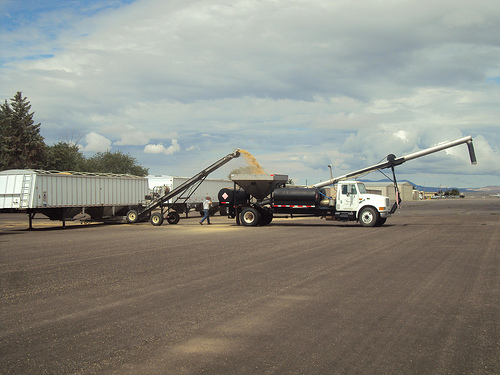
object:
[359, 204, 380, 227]
front wheel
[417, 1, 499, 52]
clouds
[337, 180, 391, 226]
cab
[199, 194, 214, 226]
man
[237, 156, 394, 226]
loaded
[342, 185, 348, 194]
side window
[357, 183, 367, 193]
windshield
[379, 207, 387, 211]
lights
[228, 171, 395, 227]
truck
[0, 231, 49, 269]
roadside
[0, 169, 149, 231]
trailer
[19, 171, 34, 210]
ladder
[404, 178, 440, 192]
mountain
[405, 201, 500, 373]
road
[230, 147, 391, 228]
loading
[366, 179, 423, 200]
buildings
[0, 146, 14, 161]
tree leaves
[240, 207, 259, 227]
rear wheels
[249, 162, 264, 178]
sand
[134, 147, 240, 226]
conveyor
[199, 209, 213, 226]
blue jeans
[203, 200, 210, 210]
white shirt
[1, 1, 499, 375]
sunny day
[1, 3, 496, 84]
blue sky